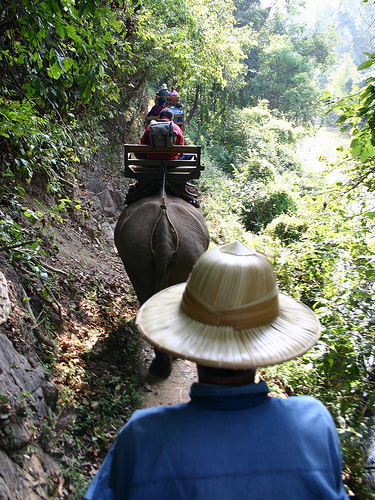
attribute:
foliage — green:
[6, 0, 252, 174]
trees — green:
[257, 32, 336, 126]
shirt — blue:
[78, 377, 350, 498]